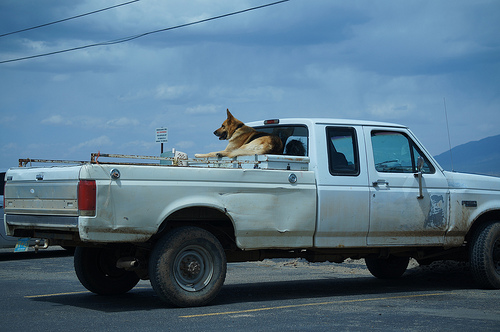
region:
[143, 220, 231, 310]
A REAR TRUCK TIRE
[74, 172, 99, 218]
A REAR BRAKE LIGHT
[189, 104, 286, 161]
A DOG ON THE BACK OF THE TRUCK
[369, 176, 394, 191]
A TRUCK DOOR HANDLE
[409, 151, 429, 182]
A SIDE VIEW MIRROR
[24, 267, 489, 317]
A SHADOW ON THE GROUND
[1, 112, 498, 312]
A WHITE PICKUP TRUCK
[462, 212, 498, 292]
A FRONT TRUCK TIRE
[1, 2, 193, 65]
POWER LINES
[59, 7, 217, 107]
CLOUDS IN THE SKY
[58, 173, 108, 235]
red tail light of truck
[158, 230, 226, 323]
black tire with gray rim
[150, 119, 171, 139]
black red and white sign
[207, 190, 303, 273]
dent in side of truck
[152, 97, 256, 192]
dog laying on tool box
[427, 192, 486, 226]
silver emblem that says f-150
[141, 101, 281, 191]
brown and black dog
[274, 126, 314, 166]
person sitting in truck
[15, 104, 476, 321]
white ruck with dog in back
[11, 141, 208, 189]
rusted white rails on truck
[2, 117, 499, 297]
An old white pickup truck.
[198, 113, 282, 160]
A dog sitting in the back.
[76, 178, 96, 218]
A red taillight.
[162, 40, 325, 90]
Part of the cloudy sky.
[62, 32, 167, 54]
A wire in the air.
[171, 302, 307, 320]
A yellow line on the road.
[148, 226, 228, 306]
A dirty black tire.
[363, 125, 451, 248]
The white passenger door.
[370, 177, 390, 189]
The silver door handle.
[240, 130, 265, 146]
The dog's black and brown fur.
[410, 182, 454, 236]
paint chipping off truck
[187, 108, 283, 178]
dog sitting in back of truck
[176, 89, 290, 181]
dog is brown and black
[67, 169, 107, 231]
truck has red tail light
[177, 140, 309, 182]
gray container in truck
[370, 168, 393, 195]
door handle is silver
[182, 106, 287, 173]
dog is laying on container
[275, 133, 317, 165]
person driving the truck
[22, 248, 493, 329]
yellow lines on road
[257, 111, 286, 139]
light on top of truck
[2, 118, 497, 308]
white extended cab pick-up truck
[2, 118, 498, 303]
white truck in parking lot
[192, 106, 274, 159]
large brown and black German Shephered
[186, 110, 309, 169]
German Shepherd sitting on toolbox of truck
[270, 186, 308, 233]
large dent in side of white truck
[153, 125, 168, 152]
sign on tall pole behind truck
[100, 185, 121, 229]
large dent in back of white truck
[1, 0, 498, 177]
blue cloudy skies over large mountain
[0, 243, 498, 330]
paved asphalt parking lot with yellow stripes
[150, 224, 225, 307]
rear passenger side tire covered in mud